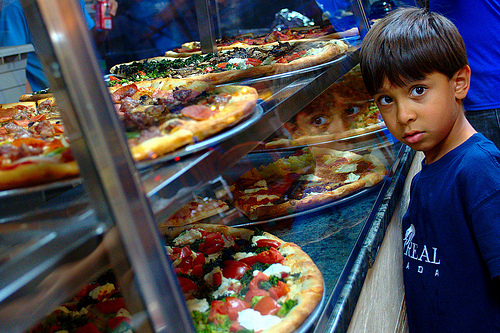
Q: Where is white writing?
A: On blue shirt.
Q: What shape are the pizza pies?
A: Round.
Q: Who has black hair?
A: The boy.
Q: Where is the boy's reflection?
A: On glass.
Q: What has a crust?
A: The pizza pies.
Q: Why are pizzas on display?
A: To be sold.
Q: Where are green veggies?
A: On the pizza pies.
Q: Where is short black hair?
A: On boy's head.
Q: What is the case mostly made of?
A: Glass.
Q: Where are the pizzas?
A: Behind the glass.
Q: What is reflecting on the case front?
A: The boy.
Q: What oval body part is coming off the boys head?
A: Ear.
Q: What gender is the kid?
A: Male.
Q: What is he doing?
A: Standing.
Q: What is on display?
A: Pizzas.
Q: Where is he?
A: Pizzeria.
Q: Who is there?
A: Little boy.